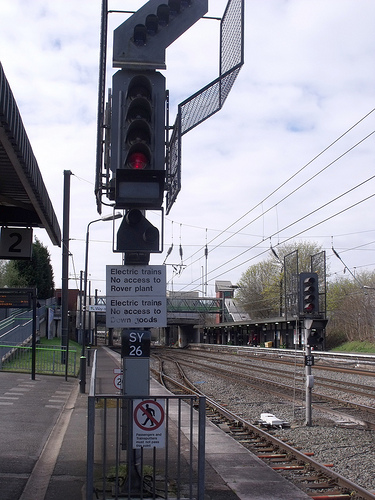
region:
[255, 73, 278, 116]
part of a cloud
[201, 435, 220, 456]
part of a floor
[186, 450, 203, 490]
part of a metal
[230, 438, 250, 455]
edge of a floor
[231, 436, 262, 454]
part of a floor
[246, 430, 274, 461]
part of a floor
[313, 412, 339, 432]
part of a ground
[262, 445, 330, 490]
train track beside platform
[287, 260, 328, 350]
traffic light on pole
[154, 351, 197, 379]
curve of intersecting train tracks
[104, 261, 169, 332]
black words on white sign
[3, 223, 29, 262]
number on white sign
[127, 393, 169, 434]
red circle with line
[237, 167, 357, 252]
wires above train tracks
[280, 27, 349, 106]
white clouds in sky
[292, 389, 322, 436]
metal pole in ground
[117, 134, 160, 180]
glowing red circular light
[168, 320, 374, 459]
four sets of electric tracks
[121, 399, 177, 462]
no walking sign beside tracks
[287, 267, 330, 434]
signals for trains on pole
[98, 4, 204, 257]
red signal lit on pole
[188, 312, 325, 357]
station platform for train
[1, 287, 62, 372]
walkway to train platform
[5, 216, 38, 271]
number two sign hanging from roof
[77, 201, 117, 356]
street lamp over train tracks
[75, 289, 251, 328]
walking bridge over train tracks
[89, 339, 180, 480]
sidewalk platform beside track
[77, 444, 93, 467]
edge of a fence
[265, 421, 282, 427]
edge of a rail way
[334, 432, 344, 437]
stone on the way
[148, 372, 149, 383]
part of a sign post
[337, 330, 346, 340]
part of the grass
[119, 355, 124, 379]
edge of a box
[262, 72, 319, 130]
storm clouds in the sky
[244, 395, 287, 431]
white object on the track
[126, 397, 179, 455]
white square sign on post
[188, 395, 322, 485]
well worn rail road track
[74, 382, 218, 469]
sturdy iron railing on pavement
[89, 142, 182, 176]
red light in traffic signal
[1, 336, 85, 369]
tall green railing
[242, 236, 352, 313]
green and black trees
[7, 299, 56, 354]
ramp leading away from the track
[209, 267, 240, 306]
brown and gray building